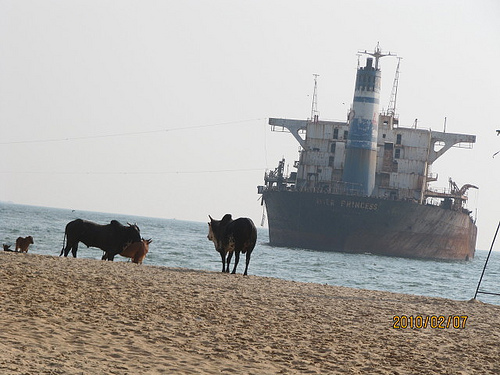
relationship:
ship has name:
[258, 45, 478, 262] [308, 196, 384, 215]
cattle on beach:
[61, 212, 258, 279] [5, 250, 493, 369]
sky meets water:
[2, 1, 254, 204] [0, 201, 192, 265]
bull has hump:
[209, 212, 258, 276] [219, 209, 235, 226]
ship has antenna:
[258, 45, 478, 262] [355, 39, 398, 70]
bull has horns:
[60, 214, 155, 268] [140, 232, 154, 250]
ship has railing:
[258, 45, 478, 262] [428, 129, 477, 150]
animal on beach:
[11, 233, 39, 253] [0, 250, 500, 375]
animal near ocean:
[11, 233, 39, 253] [4, 243, 492, 317]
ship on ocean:
[258, 45, 478, 262] [4, 243, 492, 317]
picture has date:
[2, 2, 498, 375] [391, 313, 470, 330]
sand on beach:
[137, 315, 319, 352] [0, 250, 500, 375]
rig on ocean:
[388, 58, 403, 119] [0, 199, 500, 305]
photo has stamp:
[2, 2, 498, 375] [391, 313, 470, 330]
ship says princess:
[258, 45, 478, 262] [339, 200, 381, 212]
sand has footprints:
[137, 315, 319, 352] [110, 350, 130, 363]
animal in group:
[11, 233, 39, 253] [61, 212, 258, 279]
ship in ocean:
[258, 45, 478, 262] [0, 199, 500, 305]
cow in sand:
[11, 233, 39, 253] [137, 315, 319, 352]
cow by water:
[2, 241, 13, 257] [0, 201, 192, 265]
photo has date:
[2, 2, 498, 375] [391, 313, 470, 330]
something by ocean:
[472, 223, 499, 303] [4, 243, 492, 317]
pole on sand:
[472, 223, 499, 303] [137, 315, 319, 352]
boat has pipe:
[258, 45, 478, 262] [347, 52, 381, 167]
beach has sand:
[5, 250, 493, 369] [137, 315, 319, 352]